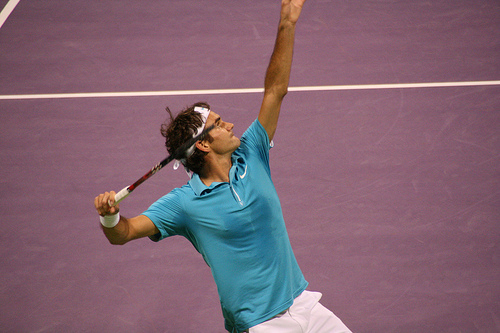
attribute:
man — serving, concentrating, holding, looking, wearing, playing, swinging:
[86, 65, 320, 262]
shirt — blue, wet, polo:
[157, 173, 346, 294]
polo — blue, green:
[147, 124, 304, 283]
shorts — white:
[255, 278, 362, 331]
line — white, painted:
[61, 69, 206, 121]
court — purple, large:
[71, 20, 269, 90]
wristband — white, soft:
[78, 202, 143, 226]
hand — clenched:
[98, 185, 135, 219]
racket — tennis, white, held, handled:
[114, 124, 212, 202]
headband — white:
[168, 95, 222, 177]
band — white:
[98, 212, 116, 222]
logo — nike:
[227, 159, 268, 199]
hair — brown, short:
[149, 93, 190, 152]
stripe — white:
[359, 76, 494, 101]